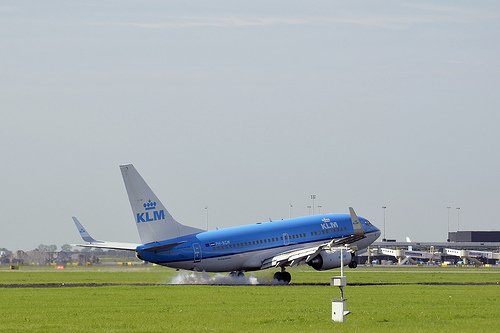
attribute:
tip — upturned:
[69, 214, 96, 240]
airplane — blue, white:
[68, 151, 382, 312]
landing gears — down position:
[224, 265, 295, 285]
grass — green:
[0, 265, 500, 330]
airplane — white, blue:
[72, 162, 380, 284]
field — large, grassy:
[1, 267, 496, 331]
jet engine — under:
[308, 244, 355, 269]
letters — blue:
[133, 206, 167, 225]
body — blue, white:
[137, 208, 385, 270]